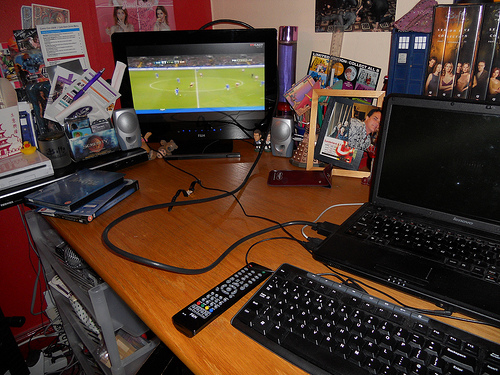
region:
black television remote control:
[167, 260, 274, 339]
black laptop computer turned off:
[312, 95, 499, 327]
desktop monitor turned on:
[111, 25, 278, 162]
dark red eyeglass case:
[265, 163, 336, 190]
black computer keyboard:
[227, 260, 498, 374]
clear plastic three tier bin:
[22, 208, 155, 373]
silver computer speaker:
[267, 114, 294, 159]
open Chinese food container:
[0, 75, 23, 160]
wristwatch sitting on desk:
[163, 178, 204, 213]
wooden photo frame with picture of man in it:
[303, 86, 385, 181]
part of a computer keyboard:
[230, 262, 496, 372]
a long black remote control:
[170, 256, 270, 332]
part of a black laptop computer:
[311, 80, 491, 325]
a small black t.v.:
[110, 26, 280, 146]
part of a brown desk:
[40, 136, 496, 371]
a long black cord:
[100, 140, 332, 286]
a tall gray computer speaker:
[110, 106, 140, 151]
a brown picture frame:
[308, 80, 380, 180]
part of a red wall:
[1, 210, 47, 329]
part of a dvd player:
[61, 142, 154, 172]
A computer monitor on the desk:
[110, 33, 280, 160]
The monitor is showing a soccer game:
[127, 46, 264, 113]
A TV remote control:
[171, 261, 268, 337]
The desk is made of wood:
[144, 221, 216, 260]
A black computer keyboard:
[230, 263, 495, 374]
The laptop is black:
[315, 96, 497, 328]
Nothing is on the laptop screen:
[379, 103, 499, 225]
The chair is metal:
[27, 210, 157, 370]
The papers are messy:
[36, 23, 122, 128]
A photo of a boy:
[308, 86, 380, 177]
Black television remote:
[172, 259, 274, 337]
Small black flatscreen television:
[111, 27, 281, 162]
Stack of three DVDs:
[22, 166, 137, 221]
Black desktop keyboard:
[230, 261, 497, 373]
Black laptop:
[313, 91, 498, 333]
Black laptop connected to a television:
[101, 26, 498, 335]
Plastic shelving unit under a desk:
[24, 207, 159, 374]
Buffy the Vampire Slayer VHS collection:
[421, 3, 498, 104]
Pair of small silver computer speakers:
[110, 104, 292, 159]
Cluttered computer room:
[0, 0, 499, 374]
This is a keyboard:
[224, 247, 498, 373]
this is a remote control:
[160, 247, 285, 346]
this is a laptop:
[300, 76, 499, 328]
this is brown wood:
[146, 225, 178, 247]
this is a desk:
[24, 103, 499, 372]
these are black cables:
[100, 116, 337, 284]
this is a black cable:
[96, 215, 202, 291]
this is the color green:
[133, 76, 141, 86]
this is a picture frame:
[302, 77, 404, 188]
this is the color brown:
[172, 226, 195, 248]